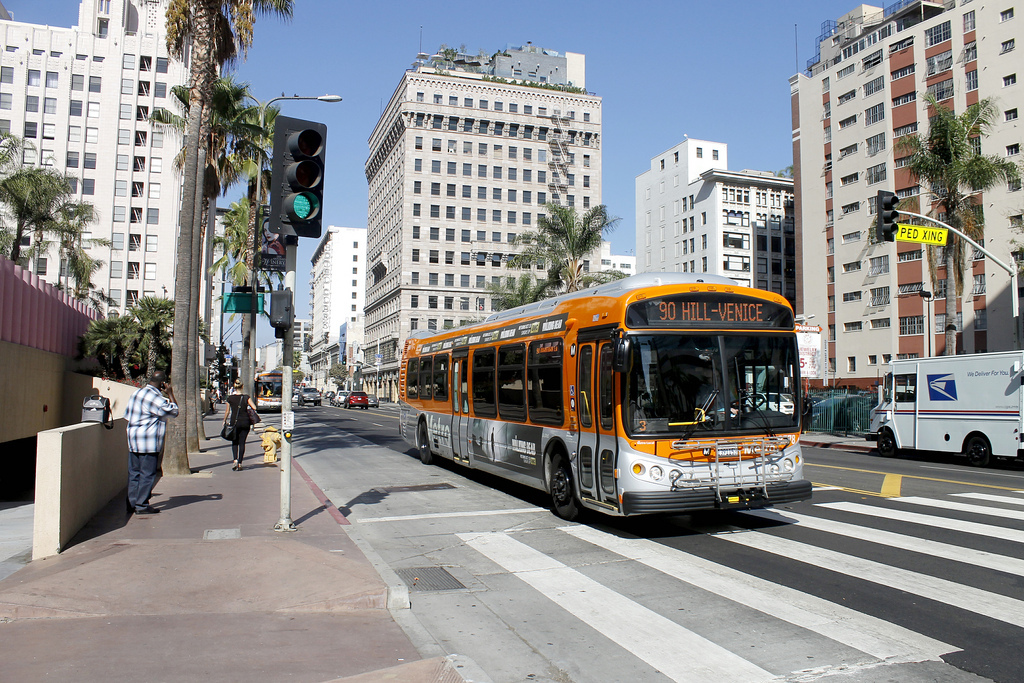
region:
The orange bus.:
[388, 278, 810, 531]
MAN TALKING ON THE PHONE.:
[125, 369, 192, 521]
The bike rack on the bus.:
[680, 439, 823, 509]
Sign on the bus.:
[651, 288, 775, 328]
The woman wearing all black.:
[218, 373, 257, 485]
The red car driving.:
[344, 385, 367, 420]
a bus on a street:
[357, 256, 813, 519]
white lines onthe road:
[493, 448, 1019, 679]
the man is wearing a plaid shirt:
[95, 369, 191, 532]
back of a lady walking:
[206, 364, 268, 472]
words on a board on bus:
[647, 287, 777, 330]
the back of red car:
[343, 373, 375, 416]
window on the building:
[586, 177, 603, 190]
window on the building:
[378, 240, 402, 247]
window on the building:
[112, 221, 139, 256]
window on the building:
[860, 282, 892, 306]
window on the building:
[571, 120, 592, 137]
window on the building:
[380, 337, 394, 367]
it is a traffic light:
[261, 117, 338, 236]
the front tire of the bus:
[539, 446, 590, 513]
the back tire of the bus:
[413, 413, 442, 456]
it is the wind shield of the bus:
[622, 338, 796, 438]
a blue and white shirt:
[126, 389, 174, 446]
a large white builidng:
[365, 46, 582, 325]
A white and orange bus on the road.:
[378, 306, 825, 516]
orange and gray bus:
[394, 289, 821, 505]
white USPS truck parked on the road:
[874, 355, 1021, 474]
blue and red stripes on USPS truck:
[899, 396, 1021, 431]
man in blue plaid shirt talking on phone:
[125, 370, 183, 508]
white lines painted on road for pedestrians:
[542, 559, 1005, 673]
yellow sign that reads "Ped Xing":
[877, 207, 957, 247]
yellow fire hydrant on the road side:
[260, 427, 280, 463]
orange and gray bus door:
[574, 332, 628, 501]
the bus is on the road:
[394, 269, 803, 536]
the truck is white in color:
[868, 345, 1014, 460]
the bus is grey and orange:
[407, 274, 806, 521]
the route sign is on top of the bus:
[656, 295, 768, 333]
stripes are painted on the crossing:
[426, 452, 1014, 678]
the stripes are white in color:
[427, 471, 1020, 677]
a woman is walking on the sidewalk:
[223, 379, 261, 465]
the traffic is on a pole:
[264, 113, 331, 534]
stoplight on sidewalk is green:
[270, 115, 328, 528]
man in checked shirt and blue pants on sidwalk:
[122, 368, 180, 515]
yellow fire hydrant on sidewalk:
[260, 421, 289, 466]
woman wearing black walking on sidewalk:
[222, 376, 261, 468]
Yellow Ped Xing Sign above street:
[893, 221, 948, 245]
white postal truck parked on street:
[870, 346, 1022, 460]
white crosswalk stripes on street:
[359, 484, 1021, 680]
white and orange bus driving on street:
[397, 278, 808, 520]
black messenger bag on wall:
[81, 393, 113, 422]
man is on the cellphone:
[127, 362, 182, 511]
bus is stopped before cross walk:
[396, 267, 812, 517]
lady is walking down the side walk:
[220, 374, 260, 466]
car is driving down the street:
[340, 390, 369, 406]